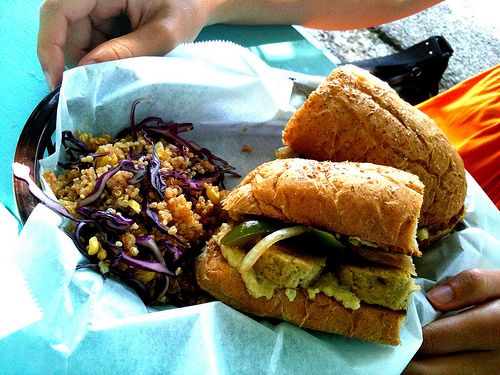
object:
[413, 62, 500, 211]
shirt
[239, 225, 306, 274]
onion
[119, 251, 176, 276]
slice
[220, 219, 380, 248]
green pepper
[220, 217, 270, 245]
skin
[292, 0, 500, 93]
bench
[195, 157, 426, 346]
sandwich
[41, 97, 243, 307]
food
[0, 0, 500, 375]
table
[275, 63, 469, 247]
food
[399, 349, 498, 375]
fingers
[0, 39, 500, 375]
white paper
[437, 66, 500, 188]
wrinkles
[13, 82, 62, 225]
basket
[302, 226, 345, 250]
pepper